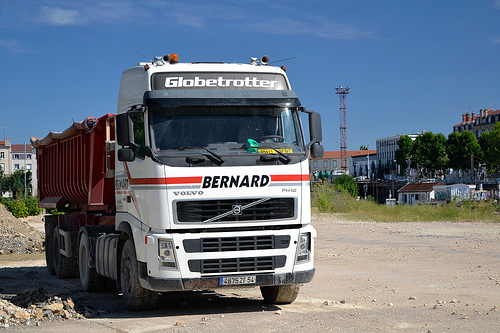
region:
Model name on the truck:
[154, 67, 293, 102]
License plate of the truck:
[214, 273, 271, 290]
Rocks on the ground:
[326, 280, 498, 324]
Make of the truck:
[166, 187, 211, 199]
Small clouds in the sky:
[17, 0, 379, 51]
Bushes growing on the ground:
[312, 175, 492, 227]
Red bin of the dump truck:
[15, 107, 120, 218]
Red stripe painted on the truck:
[121, 170, 320, 190]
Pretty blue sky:
[373, 14, 493, 91]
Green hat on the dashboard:
[237, 134, 263, 157]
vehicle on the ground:
[19, 41, 339, 326]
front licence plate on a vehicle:
[213, 268, 266, 288]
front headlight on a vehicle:
[149, 231, 189, 285]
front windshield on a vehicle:
[141, 86, 306, 173]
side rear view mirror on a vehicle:
[291, 91, 330, 171]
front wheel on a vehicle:
[108, 224, 168, 313]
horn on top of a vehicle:
[148, 48, 175, 70]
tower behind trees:
[325, 74, 365, 193]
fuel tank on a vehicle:
[87, 226, 132, 285]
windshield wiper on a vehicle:
[224, 143, 296, 165]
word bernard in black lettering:
[202, 173, 270, 190]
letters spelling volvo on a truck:
[171, 189, 203, 196]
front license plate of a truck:
[218, 275, 258, 286]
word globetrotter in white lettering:
[165, 74, 283, 91]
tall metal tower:
[332, 75, 353, 197]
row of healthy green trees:
[394, 127, 499, 178]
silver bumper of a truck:
[138, 270, 319, 289]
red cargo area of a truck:
[28, 109, 121, 225]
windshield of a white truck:
[148, 96, 305, 168]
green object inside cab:
[245, 138, 260, 155]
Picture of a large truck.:
[10, 10, 423, 323]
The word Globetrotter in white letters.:
[156, 69, 296, 97]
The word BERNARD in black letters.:
[198, 169, 274, 192]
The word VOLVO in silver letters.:
[168, 187, 209, 200]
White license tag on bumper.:
[220, 270, 262, 287]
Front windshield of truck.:
[141, 100, 308, 167]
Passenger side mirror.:
[111, 95, 143, 169]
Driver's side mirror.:
[297, 100, 339, 170]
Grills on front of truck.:
[166, 193, 296, 275]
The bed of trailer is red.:
[21, 119, 115, 211]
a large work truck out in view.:
[20, 38, 388, 324]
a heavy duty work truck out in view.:
[15, 35, 358, 313]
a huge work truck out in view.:
[15, 41, 388, 316]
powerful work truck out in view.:
[17, 10, 363, 318]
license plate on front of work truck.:
[210, 271, 265, 298]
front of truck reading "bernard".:
[187, 170, 279, 192]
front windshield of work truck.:
[142, 100, 302, 160]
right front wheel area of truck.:
[112, 241, 164, 314]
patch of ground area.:
[336, 223, 475, 306]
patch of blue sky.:
[354, 16, 470, 96]